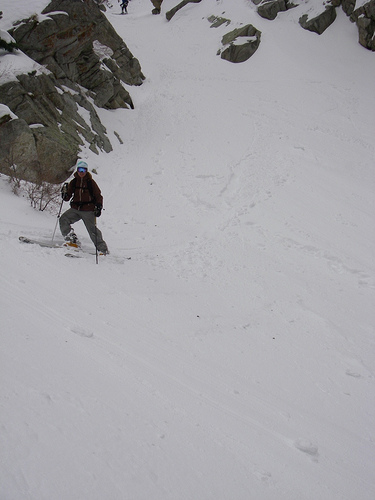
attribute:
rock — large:
[247, 0, 303, 26]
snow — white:
[327, 86, 342, 131]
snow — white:
[3, 2, 373, 499]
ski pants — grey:
[54, 202, 110, 248]